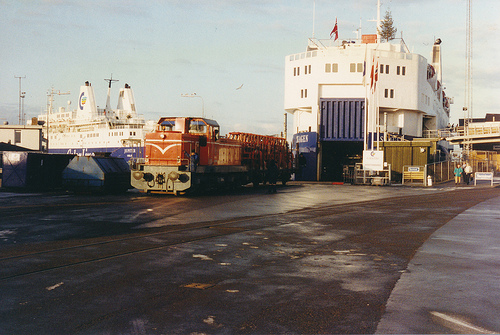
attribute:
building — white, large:
[284, 36, 442, 186]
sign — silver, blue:
[362, 145, 389, 167]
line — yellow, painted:
[152, 268, 223, 308]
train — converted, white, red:
[126, 115, 239, 191]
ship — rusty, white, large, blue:
[11, 72, 148, 183]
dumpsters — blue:
[4, 148, 127, 203]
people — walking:
[444, 151, 474, 187]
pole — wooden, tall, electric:
[8, 69, 32, 127]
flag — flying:
[328, 16, 343, 46]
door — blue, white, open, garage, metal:
[316, 94, 371, 174]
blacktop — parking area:
[19, 184, 463, 334]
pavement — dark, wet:
[30, 190, 367, 333]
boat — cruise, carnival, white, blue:
[27, 85, 148, 172]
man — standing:
[468, 164, 470, 183]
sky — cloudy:
[25, 7, 489, 116]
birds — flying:
[230, 82, 258, 93]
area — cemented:
[80, 141, 493, 302]